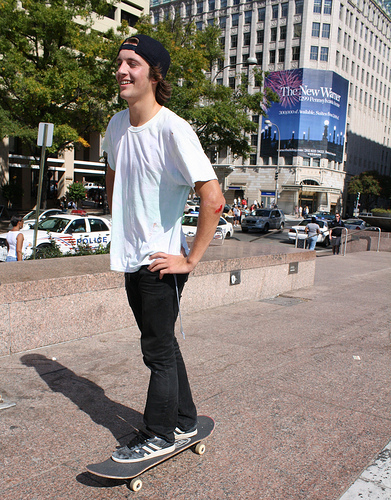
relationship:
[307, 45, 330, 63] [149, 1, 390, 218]
window on side of building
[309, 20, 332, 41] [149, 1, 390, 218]
window on side of building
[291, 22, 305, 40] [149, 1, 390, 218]
window on side of building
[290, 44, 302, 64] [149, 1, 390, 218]
window on side of building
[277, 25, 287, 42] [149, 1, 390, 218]
window on side of building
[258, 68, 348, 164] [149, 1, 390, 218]
banner hanging from building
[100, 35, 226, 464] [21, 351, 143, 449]
man has shadow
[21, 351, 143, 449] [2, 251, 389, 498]
shadow cast on ground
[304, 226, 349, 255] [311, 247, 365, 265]
handrail on sides of stairs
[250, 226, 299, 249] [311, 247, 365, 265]
handrail on sides of stairs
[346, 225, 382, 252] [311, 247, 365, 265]
handrail on sides of stairs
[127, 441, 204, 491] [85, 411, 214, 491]
wheels on bottom of skateboard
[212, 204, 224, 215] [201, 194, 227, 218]
cut on elbow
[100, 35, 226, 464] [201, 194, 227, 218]
man has elbow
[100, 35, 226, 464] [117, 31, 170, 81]
man wearing cap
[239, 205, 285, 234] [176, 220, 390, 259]
suv driving on road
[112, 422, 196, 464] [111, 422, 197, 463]
shoes have shoes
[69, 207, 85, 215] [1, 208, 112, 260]
light on top of police car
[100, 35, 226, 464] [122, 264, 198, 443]
man wearing jeans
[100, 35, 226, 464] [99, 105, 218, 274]
man wearing shirt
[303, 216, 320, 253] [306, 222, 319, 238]
woma wearing shirt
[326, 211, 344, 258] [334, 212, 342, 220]
man wearing glasses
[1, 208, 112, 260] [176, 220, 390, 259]
police car o side of road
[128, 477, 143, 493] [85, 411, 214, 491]
wheel o bottom of skateboard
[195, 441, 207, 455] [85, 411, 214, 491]
wheel o bottom of skateboard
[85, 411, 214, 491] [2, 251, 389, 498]
skateboard o top of ground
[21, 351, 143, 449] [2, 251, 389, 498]
shadow cast o ground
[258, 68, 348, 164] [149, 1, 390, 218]
banner hanging o building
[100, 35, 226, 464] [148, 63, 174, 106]
man has hair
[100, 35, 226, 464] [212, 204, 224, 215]
man has cut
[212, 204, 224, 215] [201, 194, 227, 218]
cut of elbow